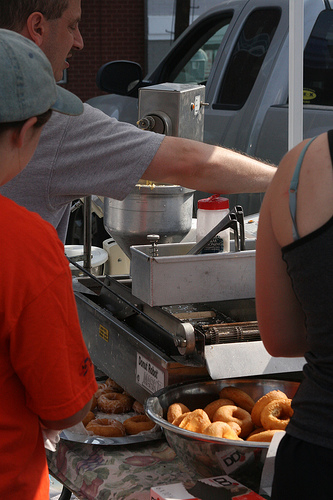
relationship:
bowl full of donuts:
[147, 379, 301, 484] [196, 396, 275, 438]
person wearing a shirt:
[2, 30, 100, 476] [2, 196, 102, 437]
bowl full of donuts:
[147, 379, 301, 484] [141, 372, 332, 466]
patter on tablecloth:
[111, 435, 166, 483] [46, 443, 227, 499]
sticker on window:
[290, 91, 314, 101] [282, 6, 331, 105]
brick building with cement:
[63, 5, 150, 86] [112, 27, 126, 28]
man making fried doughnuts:
[0, 2, 83, 82] [260, 399, 294, 429]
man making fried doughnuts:
[0, 2, 83, 82] [214, 404, 250, 423]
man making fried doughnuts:
[0, 2, 83, 82] [125, 416, 153, 434]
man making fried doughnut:
[0, 2, 83, 82] [84, 415, 123, 436]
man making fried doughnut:
[0, 2, 83, 82] [96, 391, 131, 412]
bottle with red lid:
[194, 189, 235, 253] [194, 190, 230, 208]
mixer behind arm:
[126, 87, 214, 143] [246, 195, 310, 362]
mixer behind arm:
[126, 87, 214, 143] [78, 116, 275, 203]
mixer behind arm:
[126, 87, 214, 143] [18, 328, 91, 433]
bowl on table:
[147, 379, 301, 484] [75, 369, 299, 493]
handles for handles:
[185, 203, 247, 251] [185, 203, 247, 251]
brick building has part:
[63, 5, 150, 86] [86, 7, 136, 59]